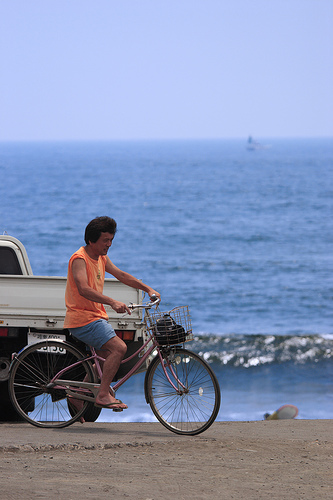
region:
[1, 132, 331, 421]
a large body of water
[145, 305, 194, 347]
a gray wire basket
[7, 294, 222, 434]
a purple bike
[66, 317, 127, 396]
the leg of a man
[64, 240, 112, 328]
a man's tank top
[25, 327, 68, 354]
part of a white license plate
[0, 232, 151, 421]
part of a white truck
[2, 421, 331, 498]
brown beach sand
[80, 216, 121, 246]
a man's short cut black hair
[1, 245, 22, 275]
part of a truck window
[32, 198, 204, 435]
man riding bike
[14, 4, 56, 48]
white clouds in blue sky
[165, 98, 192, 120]
white clouds in blue sky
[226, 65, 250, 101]
white clouds in blue sky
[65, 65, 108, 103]
white clouds in blue sky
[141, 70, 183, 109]
white clouds in blue sky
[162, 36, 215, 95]
white clouds in blue sky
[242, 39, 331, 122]
white clouds in blue sky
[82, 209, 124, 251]
man has dark hair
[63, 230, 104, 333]
man has orange shirt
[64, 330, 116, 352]
man has blue shorts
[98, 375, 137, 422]
man is wearing sandals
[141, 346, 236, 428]
black wheel on bike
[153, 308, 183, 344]
wire basket on bike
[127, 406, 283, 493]
sand is dark brown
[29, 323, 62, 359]
black and white license plate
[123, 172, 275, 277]
water is dark blue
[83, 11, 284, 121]
blue and white sky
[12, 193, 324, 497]
A person is on a bicycle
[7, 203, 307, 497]
A person is close to the ocean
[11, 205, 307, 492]
A person is riding on a beach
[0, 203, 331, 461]
A person is looking for their friend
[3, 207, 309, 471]
The bicycle has a basket in front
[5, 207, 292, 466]
The man is wearing short pants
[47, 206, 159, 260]
The man has dark colored hair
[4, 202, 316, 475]
The man is having a good time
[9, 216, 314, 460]
The man is out in the daytime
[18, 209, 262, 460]
The man is enjoying the day